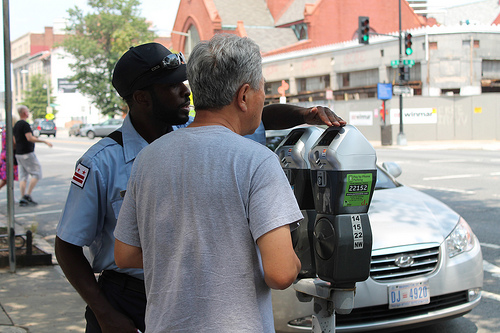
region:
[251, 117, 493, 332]
The car is silver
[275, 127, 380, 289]
The meter is grey and silver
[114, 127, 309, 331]
The man is wearing a grey tshirt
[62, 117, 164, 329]
The police officer is wearing a blue shirt and black pants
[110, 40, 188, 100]
The police officer is wearing a black hat and sunglasses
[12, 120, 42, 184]
The man in the background is wearing a black shirt and khaki shorts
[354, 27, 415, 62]
The traffic lights are now green .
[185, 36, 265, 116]
the man's hair is gray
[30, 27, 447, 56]
the roof is red on the building in the back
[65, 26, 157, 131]
the tree is green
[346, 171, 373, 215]
Green sticker on meter.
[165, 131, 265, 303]
Gray t-shirt of man standing next to meter monitor guy.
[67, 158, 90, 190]
White patch with red design on blue shirt of meter man.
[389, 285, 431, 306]
License plate on gray car.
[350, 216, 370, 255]
White sticker below green sticker on parking meter.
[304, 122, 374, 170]
Parking meter screen the men are looking at.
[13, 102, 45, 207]
Bald man in a black t-shirt standing in street.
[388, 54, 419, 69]
Green street sign below traffic light.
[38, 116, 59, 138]
Gray van driving up the block.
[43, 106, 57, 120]
Yellow sign up the block next to the gray van.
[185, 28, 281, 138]
a man with grey hair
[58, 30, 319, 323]
two men standing next to each other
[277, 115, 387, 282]
modern parking meters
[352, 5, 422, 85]
green stop lights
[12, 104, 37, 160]
a person in black shirt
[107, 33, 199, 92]
black hat with sunglasses on it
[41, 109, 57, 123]
a yellow sign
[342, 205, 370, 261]
numbers on the side of parking meter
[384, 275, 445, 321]
a license plate on a car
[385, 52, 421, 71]
a green street sign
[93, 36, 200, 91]
This is a black hat.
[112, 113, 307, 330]
This is a tshirt on a man.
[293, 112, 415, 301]
This is a meter.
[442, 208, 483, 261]
This is a headlight.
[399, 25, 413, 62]
This is a street light.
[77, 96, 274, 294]
This is a uniform.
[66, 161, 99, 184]
This is a patch.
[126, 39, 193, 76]
These are sunglasses.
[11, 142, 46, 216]
These are shorts.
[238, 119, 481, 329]
This is a car.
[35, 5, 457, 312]
Two men in front of parking meters.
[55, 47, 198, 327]
The man on left is in uniform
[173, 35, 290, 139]
An older man with grey hair.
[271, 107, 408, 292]
Two parking meters.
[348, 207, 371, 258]
Numbers on a white tag.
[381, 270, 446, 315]
License plate on front of car.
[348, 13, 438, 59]
Two traffic lights.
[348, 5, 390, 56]
The traffic light is green.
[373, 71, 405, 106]
A square blue sign.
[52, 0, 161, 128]
A green tree in background.